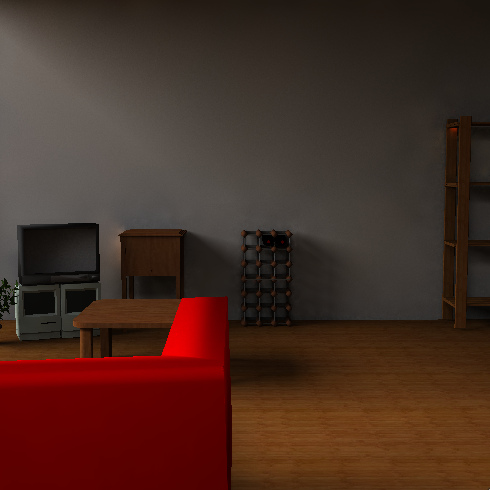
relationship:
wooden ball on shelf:
[239, 223, 253, 243] [215, 219, 306, 265]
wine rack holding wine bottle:
[240, 228, 295, 330] [256, 233, 272, 253]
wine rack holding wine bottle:
[240, 228, 295, 330] [273, 233, 291, 255]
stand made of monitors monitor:
[7, 272, 106, 354] [12, 283, 62, 341]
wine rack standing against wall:
[238, 228, 295, 327] [173, 38, 426, 226]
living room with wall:
[7, 2, 488, 489] [0, 0, 490, 322]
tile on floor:
[237, 312, 486, 487] [1, 319, 487, 489]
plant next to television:
[0, 278, 23, 328] [16, 222, 100, 284]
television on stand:
[12, 219, 100, 283] [12, 285, 103, 340]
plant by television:
[0, 276, 23, 328] [16, 222, 100, 284]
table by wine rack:
[113, 219, 194, 294] [231, 217, 294, 333]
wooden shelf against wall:
[440, 112, 487, 333] [291, 64, 486, 320]